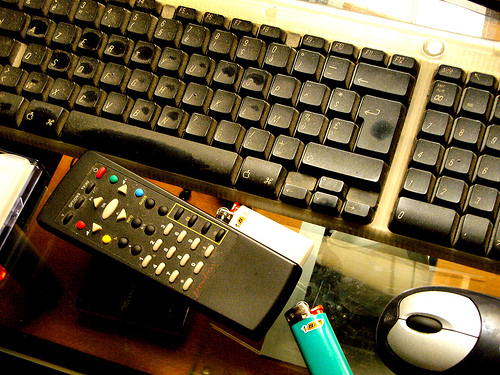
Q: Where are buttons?
A: On remote control.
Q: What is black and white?
A: Computer mouse.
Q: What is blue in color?
A: Lighter.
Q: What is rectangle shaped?
A: Remote control.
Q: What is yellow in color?
A: A button on the remote.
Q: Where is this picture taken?
A: A desk.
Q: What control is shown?
A: Remote.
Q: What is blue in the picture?
A: Lighter.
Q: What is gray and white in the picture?
A: A mouse.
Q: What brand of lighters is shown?
A: BIC.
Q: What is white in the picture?
A: A lighter.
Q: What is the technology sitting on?
A: A desk.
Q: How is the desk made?
A: Of wood.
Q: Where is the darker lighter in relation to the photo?
A: Bottom.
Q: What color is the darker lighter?
A: Green.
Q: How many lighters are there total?
A: Two.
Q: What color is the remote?
A: Black.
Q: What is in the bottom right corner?
A: Mouse.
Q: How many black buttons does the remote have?
A: Thirteen.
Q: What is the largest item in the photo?
A: Keyboard.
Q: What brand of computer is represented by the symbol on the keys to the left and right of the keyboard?
A: Apple.